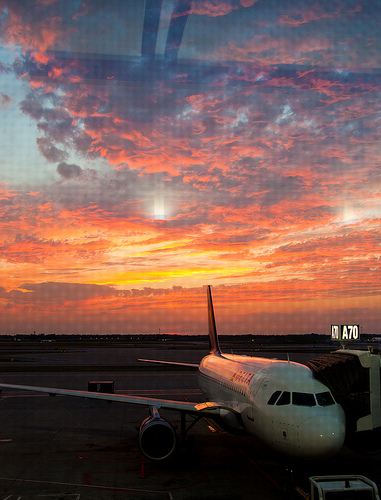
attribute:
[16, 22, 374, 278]
sky — cloudy, grey, orange, beautiful, sunset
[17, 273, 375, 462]
plane — big, white, passenger, parked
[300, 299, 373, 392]
terminal — lighted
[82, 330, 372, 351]
lights — blue, dark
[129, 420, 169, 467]
engine — large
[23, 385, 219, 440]
wing — white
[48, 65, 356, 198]
clouds — unique, purple, red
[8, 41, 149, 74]
lines — dark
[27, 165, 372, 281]
sunset — orange, colorful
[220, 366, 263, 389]
logo — red, delta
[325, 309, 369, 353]
sign — a70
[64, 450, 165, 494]
cone — orange